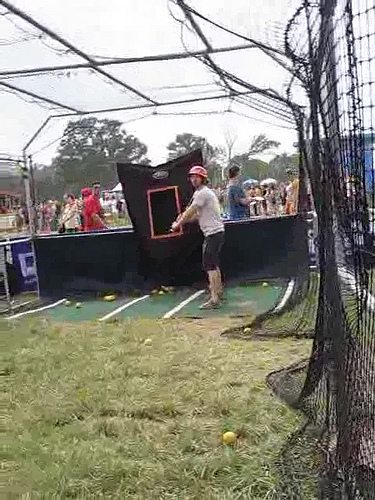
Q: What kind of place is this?
A: It is a pen.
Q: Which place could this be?
A: It is a pen.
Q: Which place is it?
A: It is a pen.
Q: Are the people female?
A: No, they are both male and female.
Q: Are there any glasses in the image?
A: No, there are no glasses.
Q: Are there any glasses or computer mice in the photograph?
A: No, there are no glasses or computer mice.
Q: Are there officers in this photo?
A: No, there are no officers.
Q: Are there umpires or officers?
A: No, there are no officers or umpires.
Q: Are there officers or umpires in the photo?
A: No, there are no officers or umpires.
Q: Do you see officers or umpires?
A: No, there are no officers or umpires.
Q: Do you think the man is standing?
A: Yes, the man is standing.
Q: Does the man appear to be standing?
A: Yes, the man is standing.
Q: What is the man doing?
A: The man is standing.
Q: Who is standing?
A: The man is standing.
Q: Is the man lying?
A: No, the man is standing.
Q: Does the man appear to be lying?
A: No, the man is standing.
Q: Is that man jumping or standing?
A: The man is standing.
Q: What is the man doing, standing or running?
A: The man is standing.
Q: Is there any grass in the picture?
A: Yes, there is grass.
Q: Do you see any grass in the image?
A: Yes, there is grass.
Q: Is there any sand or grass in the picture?
A: Yes, there is grass.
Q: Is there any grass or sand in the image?
A: Yes, there is grass.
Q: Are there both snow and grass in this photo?
A: No, there is grass but no snow.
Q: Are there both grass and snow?
A: No, there is grass but no snow.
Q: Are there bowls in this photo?
A: No, there are no bowls.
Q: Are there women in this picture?
A: Yes, there is a woman.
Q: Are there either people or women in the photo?
A: Yes, there is a woman.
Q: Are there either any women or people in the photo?
A: Yes, there is a woman.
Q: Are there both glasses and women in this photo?
A: No, there is a woman but no glasses.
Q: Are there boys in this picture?
A: No, there are no boys.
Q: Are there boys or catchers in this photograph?
A: No, there are no boys or catchers.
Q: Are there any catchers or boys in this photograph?
A: No, there are no boys or catchers.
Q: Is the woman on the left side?
A: Yes, the woman is on the left of the image.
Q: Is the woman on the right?
A: No, the woman is on the left of the image.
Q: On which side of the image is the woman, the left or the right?
A: The woman is on the left of the image.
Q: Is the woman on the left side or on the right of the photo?
A: The woman is on the left of the image.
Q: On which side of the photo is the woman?
A: The woman is on the left of the image.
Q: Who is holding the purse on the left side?
A: The woman is holding the purse.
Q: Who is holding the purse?
A: The woman is holding the purse.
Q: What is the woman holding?
A: The woman is holding the purse.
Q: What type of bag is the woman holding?
A: The woman is holding the purse.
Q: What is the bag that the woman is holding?
A: The bag is a purse.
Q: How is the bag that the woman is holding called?
A: The bag is a purse.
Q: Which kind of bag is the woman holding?
A: The woman is holding the purse.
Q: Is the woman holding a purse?
A: Yes, the woman is holding a purse.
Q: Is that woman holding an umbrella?
A: No, the woman is holding a purse.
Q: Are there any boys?
A: No, there are no boys.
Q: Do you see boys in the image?
A: No, there are no boys.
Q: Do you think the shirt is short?
A: Yes, the shirt is short.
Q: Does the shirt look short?
A: Yes, the shirt is short.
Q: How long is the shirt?
A: The shirt is short.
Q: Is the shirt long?
A: No, the shirt is short.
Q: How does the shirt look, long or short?
A: The shirt is short.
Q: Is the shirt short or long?
A: The shirt is short.